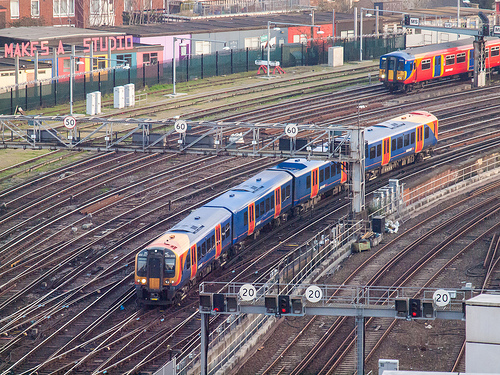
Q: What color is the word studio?
A: Pink.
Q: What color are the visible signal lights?
A: Red.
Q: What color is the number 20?
A: Black.